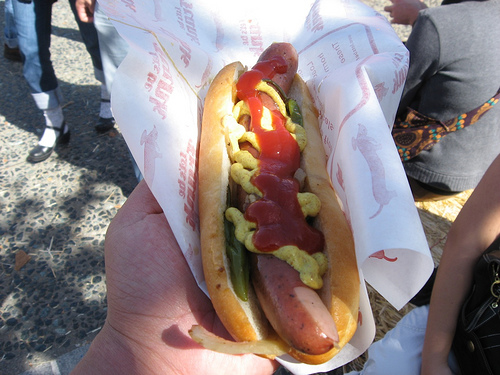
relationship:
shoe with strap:
[34, 106, 67, 174] [28, 121, 66, 139]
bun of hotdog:
[198, 62, 360, 367] [194, 39, 365, 362]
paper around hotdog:
[81, 10, 442, 362] [216, 35, 398, 350]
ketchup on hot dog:
[223, 77, 304, 256] [181, 39, 361, 369]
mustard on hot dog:
[225, 82, 332, 282] [181, 39, 361, 369]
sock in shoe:
[27, 87, 75, 149] [17, 125, 68, 167]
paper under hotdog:
[81, 10, 442, 362] [194, 39, 365, 362]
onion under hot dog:
[181, 320, 288, 361] [184, 41, 377, 370]